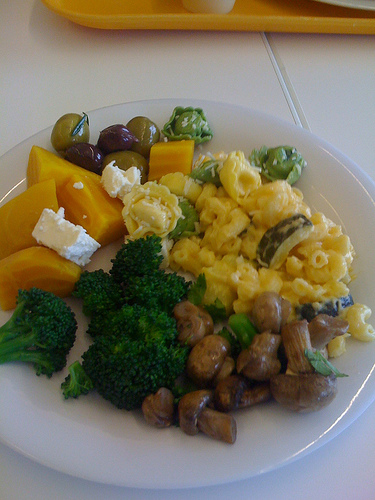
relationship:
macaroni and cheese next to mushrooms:
[172, 154, 360, 316] [141, 292, 353, 443]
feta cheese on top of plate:
[30, 207, 103, 269] [0, 98, 373, 491]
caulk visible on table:
[261, 33, 301, 128] [0, 1, 373, 500]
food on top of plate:
[1, 107, 374, 445] [0, 98, 373, 491]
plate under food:
[0, 98, 373, 491] [1, 107, 374, 445]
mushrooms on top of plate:
[141, 292, 353, 443] [0, 98, 373, 491]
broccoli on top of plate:
[2, 233, 193, 411] [0, 98, 373, 491]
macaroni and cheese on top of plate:
[172, 154, 360, 316] [0, 98, 373, 491]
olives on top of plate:
[52, 113, 162, 184] [0, 98, 373, 491]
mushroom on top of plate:
[176, 390, 238, 445] [0, 98, 373, 491]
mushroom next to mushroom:
[176, 390, 238, 445] [185, 333, 238, 387]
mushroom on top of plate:
[185, 333, 238, 387] [0, 98, 373, 491]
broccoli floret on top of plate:
[61, 361, 93, 399] [0, 98, 373, 491]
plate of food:
[0, 98, 373, 491] [1, 107, 374, 445]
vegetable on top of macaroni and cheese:
[254, 215, 319, 270] [172, 154, 360, 316]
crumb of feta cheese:
[73, 182, 83, 191] [30, 207, 103, 269]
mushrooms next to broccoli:
[141, 292, 353, 443] [2, 233, 193, 411]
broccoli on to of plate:
[2, 233, 193, 411] [0, 98, 373, 491]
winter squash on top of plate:
[0, 140, 197, 313] [0, 98, 373, 491]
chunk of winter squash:
[148, 142, 198, 180] [0, 140, 197, 313]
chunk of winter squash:
[57, 170, 128, 245] [0, 140, 197, 313]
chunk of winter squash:
[1, 246, 83, 311] [0, 140, 197, 313]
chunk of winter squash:
[0, 178, 64, 262] [0, 140, 197, 313]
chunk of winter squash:
[27, 145, 100, 192] [0, 140, 197, 313]